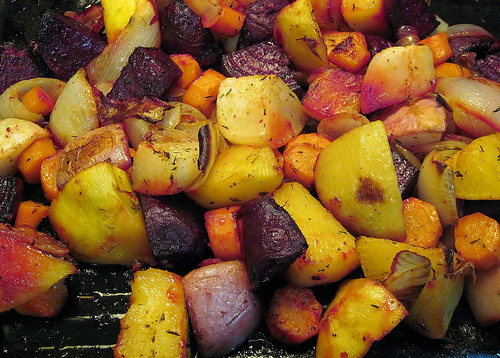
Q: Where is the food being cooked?
A: On the grill.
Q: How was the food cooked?
A: Grilled.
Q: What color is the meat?
A: Brown?.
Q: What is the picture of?
A: Food on the grill.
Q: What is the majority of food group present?
A: Vegetables.